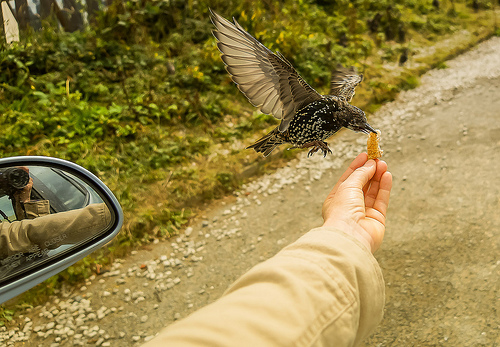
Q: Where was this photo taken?
A: On a road.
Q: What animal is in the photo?
A: A bird.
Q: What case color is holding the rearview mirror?
A: Gray.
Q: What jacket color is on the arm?
A: Beige.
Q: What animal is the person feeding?
A: Bird.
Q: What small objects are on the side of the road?
A: Gravel.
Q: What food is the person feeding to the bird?
A: Bread.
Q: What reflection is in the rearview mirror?
A: Person reaching out window.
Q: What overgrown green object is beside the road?
A: Grass.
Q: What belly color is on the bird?
A: Black with white speckles.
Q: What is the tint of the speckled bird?
A: Brown and white.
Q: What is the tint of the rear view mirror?
A: Silver.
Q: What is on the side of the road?
A: Grass.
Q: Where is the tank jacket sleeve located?
A: On an arm.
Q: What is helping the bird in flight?
A: A wing.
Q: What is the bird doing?
A: Taking food from outstrecthed hand.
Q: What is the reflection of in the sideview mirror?
A: Of a photographer.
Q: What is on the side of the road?
A: Lots of greenery.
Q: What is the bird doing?
A: Taking food.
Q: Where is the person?
A: In a car.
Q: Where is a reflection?
A: Mirror.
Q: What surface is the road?
A: Gravel.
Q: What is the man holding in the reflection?
A: Camera.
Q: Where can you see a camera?
A: Mirror.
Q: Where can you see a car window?
A: Mirror.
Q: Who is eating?
A: A bird.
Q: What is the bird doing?
A: Eating.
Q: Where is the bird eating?
A: From a hand.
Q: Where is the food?
A: On the hand.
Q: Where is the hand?
A: Reaching out of a car.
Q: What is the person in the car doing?
A: Taking a picture.